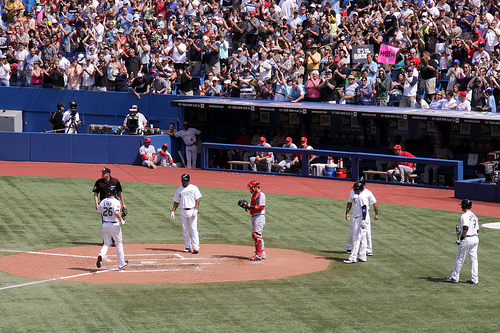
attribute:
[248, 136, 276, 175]
player — sitting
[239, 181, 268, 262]
player — padded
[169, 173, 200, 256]
person — white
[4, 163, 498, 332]
field — green, grassy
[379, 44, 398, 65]
sign — pink, up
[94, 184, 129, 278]
player — running, heading home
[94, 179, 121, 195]
shirt — black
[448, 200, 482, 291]
player — carrying bat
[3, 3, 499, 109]
spectator — watching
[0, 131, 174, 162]
fence — blue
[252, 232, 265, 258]
pad — red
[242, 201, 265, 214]
arm — bent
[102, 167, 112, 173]
cap — black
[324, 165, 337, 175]
cooler — blue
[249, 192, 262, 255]
equipment — protective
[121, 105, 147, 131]
person — videotaping